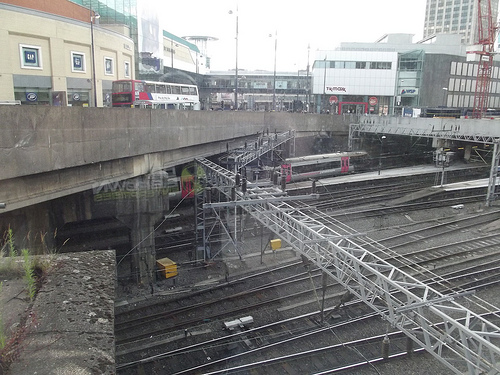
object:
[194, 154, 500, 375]
truss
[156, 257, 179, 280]
box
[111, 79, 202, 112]
bus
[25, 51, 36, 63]
sign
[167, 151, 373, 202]
train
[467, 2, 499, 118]
crane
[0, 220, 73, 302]
weeds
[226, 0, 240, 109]
lamps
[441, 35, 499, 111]
building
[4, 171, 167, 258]
base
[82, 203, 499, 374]
tracks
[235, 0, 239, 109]
poles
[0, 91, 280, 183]
bridge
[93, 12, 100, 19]
lights